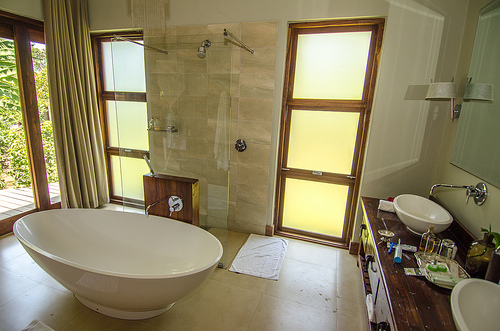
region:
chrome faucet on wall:
[429, 181, 486, 206]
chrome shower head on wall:
[196, 37, 211, 58]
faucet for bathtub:
[144, 197, 164, 219]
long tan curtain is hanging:
[40, 0, 110, 206]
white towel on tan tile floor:
[226, 230, 287, 280]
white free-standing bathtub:
[11, 205, 221, 320]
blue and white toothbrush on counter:
[392, 236, 402, 261]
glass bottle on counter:
[416, 223, 436, 249]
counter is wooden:
[360, 195, 492, 328]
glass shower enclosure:
[108, 30, 240, 238]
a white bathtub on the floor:
[16, 210, 228, 320]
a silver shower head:
[195, 35, 222, 67]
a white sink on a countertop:
[394, 185, 457, 233]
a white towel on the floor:
[234, 225, 301, 292]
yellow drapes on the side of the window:
[33, 0, 120, 210]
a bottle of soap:
[419, 223, 437, 255]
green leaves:
[481, 224, 497, 248]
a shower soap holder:
[144, 109, 176, 136]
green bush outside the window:
[1, 117, 59, 182]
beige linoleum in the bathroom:
[208, 282, 333, 326]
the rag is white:
[261, 250, 270, 273]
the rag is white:
[258, 259, 272, 284]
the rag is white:
[256, 256, 265, 266]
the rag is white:
[256, 227, 266, 253]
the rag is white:
[260, 248, 262, 259]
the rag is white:
[251, 257, 265, 271]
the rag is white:
[253, 251, 268, 283]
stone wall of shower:
[136, 22, 283, 230]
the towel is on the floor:
[223, 231, 299, 291]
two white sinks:
[391, 183, 497, 328]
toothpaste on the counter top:
[388, 240, 420, 252]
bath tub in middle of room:
[16, 189, 242, 302]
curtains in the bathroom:
[23, 2, 128, 208]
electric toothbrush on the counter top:
[394, 238, 406, 268]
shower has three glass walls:
[111, 26, 253, 227]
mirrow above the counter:
[450, 28, 497, 193]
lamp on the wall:
[423, 75, 450, 124]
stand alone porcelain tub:
[14, 206, 222, 320]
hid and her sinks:
[392, 187, 499, 328]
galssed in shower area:
[109, 24, 253, 247]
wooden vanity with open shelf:
[353, 189, 498, 329]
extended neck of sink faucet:
[426, 176, 486, 211]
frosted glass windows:
[276, 31, 373, 244]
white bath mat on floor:
[227, 229, 287, 278]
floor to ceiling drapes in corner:
[36, 5, 120, 207]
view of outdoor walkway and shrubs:
[0, 34, 67, 211]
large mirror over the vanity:
[444, 9, 496, 189]